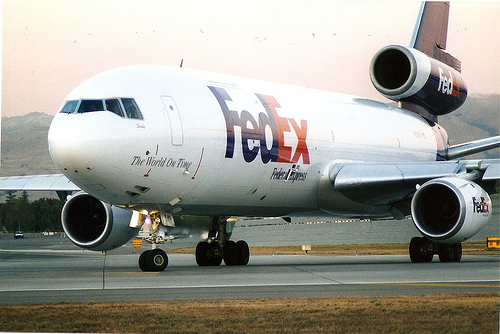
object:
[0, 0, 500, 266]
jets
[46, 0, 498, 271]
plane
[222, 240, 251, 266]
wheels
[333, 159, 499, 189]
wing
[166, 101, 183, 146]
door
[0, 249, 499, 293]
runway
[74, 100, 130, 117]
cockpit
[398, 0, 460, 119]
tail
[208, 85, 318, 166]
letters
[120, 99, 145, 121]
window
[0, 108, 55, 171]
mountains